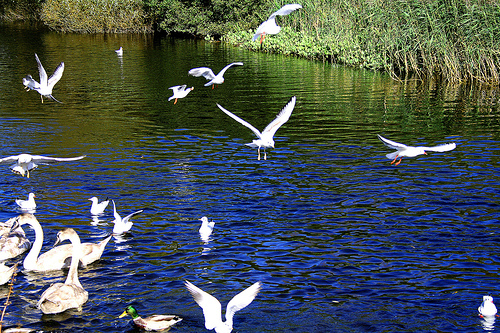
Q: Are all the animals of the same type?
A: Yes, all the animals are birds.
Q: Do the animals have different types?
A: No, all the animals are birds.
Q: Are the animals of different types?
A: No, all the animals are birds.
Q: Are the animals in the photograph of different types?
A: No, all the animals are birds.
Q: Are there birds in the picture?
A: Yes, there is a bird.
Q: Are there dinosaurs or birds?
A: Yes, there is a bird.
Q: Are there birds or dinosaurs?
A: Yes, there is a bird.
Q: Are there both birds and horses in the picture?
A: No, there is a bird but no horses.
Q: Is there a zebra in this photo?
A: No, there are no zebras.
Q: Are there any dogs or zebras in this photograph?
A: No, there are no zebras or dogs.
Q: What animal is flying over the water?
A: The animal is a bird.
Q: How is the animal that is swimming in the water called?
A: The animal is a bird.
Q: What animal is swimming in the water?
A: The animal is a bird.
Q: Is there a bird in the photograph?
A: Yes, there is a bird.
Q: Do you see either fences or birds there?
A: Yes, there is a bird.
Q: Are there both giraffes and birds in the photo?
A: No, there is a bird but no giraffes.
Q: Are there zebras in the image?
A: No, there are no zebras.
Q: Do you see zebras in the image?
A: No, there are no zebras.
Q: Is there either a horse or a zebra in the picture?
A: No, there are no zebras or horses.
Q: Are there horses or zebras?
A: No, there are no zebras or horses.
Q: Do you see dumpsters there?
A: No, there are no dumpsters.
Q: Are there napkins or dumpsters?
A: No, there are no dumpsters or napkins.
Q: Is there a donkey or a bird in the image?
A: Yes, there is a bird.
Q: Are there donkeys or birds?
A: Yes, there is a bird.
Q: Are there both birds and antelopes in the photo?
A: No, there is a bird but no antelopes.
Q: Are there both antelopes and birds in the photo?
A: No, there is a bird but no antelopes.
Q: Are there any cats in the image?
A: No, there are no cats.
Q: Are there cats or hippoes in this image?
A: No, there are no cats or hippoes.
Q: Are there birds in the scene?
A: Yes, there is a bird.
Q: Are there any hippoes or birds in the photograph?
A: Yes, there is a bird.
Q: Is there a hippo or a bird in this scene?
A: Yes, there is a bird.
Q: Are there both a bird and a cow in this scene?
A: No, there is a bird but no cows.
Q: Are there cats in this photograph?
A: No, there are no cats.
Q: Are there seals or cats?
A: No, there are no cats or seals.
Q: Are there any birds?
A: Yes, there is a bird.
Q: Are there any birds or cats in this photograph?
A: Yes, there is a bird.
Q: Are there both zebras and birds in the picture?
A: No, there is a bird but no zebras.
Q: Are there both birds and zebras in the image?
A: No, there is a bird but no zebras.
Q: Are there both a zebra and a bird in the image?
A: No, there is a bird but no zebras.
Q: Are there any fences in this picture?
A: No, there are no fences.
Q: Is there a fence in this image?
A: No, there are no fences.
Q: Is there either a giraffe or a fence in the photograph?
A: No, there are no fences or giraffes.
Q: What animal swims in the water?
A: The animal is a bird.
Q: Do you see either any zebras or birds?
A: Yes, there is a bird.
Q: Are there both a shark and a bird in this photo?
A: No, there is a bird but no sharks.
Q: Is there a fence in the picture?
A: No, there are no fences.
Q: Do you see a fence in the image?
A: No, there are no fences.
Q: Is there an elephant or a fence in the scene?
A: No, there are no fences or elephants.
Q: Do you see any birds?
A: Yes, there is a bird.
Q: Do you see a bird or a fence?
A: Yes, there is a bird.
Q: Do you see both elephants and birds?
A: No, there is a bird but no elephants.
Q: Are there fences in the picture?
A: No, there are no fences.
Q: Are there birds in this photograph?
A: Yes, there is a bird.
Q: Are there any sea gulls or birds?
A: Yes, there is a bird.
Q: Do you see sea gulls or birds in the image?
A: Yes, there is a bird.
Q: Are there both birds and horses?
A: No, there is a bird but no horses.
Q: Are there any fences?
A: No, there are no fences.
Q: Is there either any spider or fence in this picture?
A: No, there are no fences or spiders.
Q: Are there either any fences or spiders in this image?
A: No, there are no fences or spiders.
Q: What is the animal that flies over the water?
A: The animal is a bird.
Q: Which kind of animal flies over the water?
A: The animal is a bird.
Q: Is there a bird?
A: Yes, there is a bird.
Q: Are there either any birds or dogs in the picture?
A: Yes, there is a bird.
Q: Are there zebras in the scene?
A: No, there are no zebras.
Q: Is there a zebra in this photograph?
A: No, there are no zebras.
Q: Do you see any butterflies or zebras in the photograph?
A: No, there are no zebras or butterflies.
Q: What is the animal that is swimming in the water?
A: The animal is a bird.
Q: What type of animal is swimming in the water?
A: The animal is a bird.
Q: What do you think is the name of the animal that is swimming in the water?
A: The animal is a bird.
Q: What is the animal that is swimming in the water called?
A: The animal is a bird.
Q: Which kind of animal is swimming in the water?
A: The animal is a bird.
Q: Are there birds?
A: Yes, there are birds.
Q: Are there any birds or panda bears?
A: Yes, there are birds.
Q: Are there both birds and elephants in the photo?
A: No, there are birds but no elephants.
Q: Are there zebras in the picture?
A: No, there are no zebras.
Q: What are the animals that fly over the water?
A: The animals are birds.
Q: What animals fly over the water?
A: The animals are birds.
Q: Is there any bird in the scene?
A: Yes, there is a bird.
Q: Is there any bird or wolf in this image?
A: Yes, there is a bird.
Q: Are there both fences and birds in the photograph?
A: No, there is a bird but no fences.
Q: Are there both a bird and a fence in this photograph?
A: No, there is a bird but no fences.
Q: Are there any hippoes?
A: No, there are no hippoes.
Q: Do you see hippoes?
A: No, there are no hippoes.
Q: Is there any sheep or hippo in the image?
A: No, there are no hippoes or sheep.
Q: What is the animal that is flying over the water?
A: The animal is a bird.